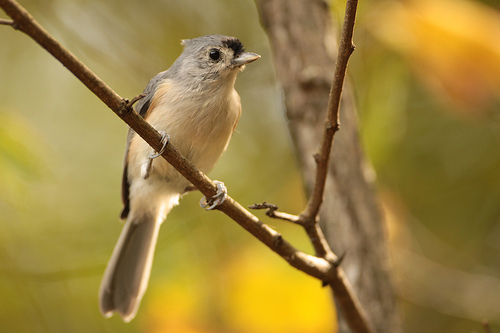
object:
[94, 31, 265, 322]
bird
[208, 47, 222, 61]
eye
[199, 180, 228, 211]
claw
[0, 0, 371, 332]
tree branch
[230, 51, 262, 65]
beak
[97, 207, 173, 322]
tail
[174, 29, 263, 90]
head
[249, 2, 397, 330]
trunk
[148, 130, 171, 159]
foot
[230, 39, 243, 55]
spot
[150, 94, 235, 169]
breast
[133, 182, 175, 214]
feather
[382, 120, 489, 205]
leaves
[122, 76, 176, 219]
wing